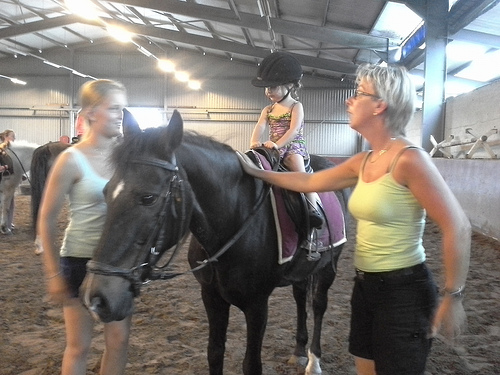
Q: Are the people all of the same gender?
A: Yes, all the people are female.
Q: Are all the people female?
A: Yes, all the people are female.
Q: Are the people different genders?
A: No, all the people are female.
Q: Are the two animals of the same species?
A: Yes, all the animals are horses.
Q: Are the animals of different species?
A: No, all the animals are horses.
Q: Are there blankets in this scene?
A: Yes, there is a blanket.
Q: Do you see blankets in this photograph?
A: Yes, there is a blanket.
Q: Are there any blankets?
A: Yes, there is a blanket.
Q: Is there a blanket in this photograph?
A: Yes, there is a blanket.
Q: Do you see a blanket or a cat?
A: Yes, there is a blanket.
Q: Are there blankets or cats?
A: Yes, there is a blanket.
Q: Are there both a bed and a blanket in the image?
A: No, there is a blanket but no beds.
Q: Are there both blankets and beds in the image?
A: No, there is a blanket but no beds.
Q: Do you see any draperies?
A: No, there are no draperies.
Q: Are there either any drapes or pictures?
A: No, there are no drapes or pictures.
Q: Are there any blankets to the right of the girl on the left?
A: Yes, there is a blanket to the right of the girl.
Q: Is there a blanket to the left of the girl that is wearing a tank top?
A: No, the blanket is to the right of the girl.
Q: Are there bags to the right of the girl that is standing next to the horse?
A: No, there is a blanket to the right of the girl.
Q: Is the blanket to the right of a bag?
A: No, the blanket is to the right of a girl.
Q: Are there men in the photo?
A: No, there are no men.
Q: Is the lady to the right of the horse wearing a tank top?
A: Yes, the lady is wearing a tank top.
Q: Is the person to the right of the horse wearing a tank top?
A: Yes, the lady is wearing a tank top.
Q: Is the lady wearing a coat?
A: No, the lady is wearing a tank top.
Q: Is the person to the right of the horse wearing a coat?
A: No, the lady is wearing a tank top.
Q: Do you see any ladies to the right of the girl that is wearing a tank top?
A: Yes, there is a lady to the right of the girl.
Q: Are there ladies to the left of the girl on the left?
A: No, the lady is to the right of the girl.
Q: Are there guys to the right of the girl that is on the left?
A: No, there is a lady to the right of the girl.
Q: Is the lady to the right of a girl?
A: Yes, the lady is to the right of a girl.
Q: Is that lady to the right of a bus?
A: No, the lady is to the right of a girl.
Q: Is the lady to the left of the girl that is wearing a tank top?
A: No, the lady is to the right of the girl.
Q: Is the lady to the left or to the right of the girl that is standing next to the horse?
A: The lady is to the right of the girl.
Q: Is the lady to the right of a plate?
A: No, the lady is to the right of the horse.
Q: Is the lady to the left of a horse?
A: No, the lady is to the right of a horse.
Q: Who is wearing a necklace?
A: The lady is wearing a necklace.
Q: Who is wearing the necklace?
A: The lady is wearing a necklace.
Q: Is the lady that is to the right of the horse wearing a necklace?
A: Yes, the lady is wearing a necklace.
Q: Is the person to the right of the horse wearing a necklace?
A: Yes, the lady is wearing a necklace.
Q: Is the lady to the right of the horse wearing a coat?
A: No, the lady is wearing a necklace.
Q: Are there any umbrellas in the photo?
A: No, there are no umbrellas.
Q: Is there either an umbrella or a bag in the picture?
A: No, there are no umbrellas or bags.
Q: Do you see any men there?
A: No, there are no men.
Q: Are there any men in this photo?
A: No, there are no men.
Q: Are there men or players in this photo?
A: No, there are no men or players.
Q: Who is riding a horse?
A: The girl is riding a horse.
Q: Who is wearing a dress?
A: The girl is wearing a dress.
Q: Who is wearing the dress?
A: The girl is wearing a dress.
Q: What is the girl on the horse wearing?
A: The girl is wearing a dress.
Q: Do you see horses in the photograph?
A: Yes, there is a horse.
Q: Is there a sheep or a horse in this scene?
A: Yes, there is a horse.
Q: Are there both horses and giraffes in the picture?
A: No, there is a horse but no giraffes.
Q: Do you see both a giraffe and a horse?
A: No, there is a horse but no giraffes.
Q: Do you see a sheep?
A: No, there is no sheep.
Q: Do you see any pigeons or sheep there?
A: No, there are no sheep or pigeons.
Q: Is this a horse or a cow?
A: This is a horse.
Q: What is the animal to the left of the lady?
A: The animal is a horse.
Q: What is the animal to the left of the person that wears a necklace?
A: The animal is a horse.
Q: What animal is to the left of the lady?
A: The animal is a horse.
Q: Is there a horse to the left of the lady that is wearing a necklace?
A: Yes, there is a horse to the left of the lady.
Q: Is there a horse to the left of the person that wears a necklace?
A: Yes, there is a horse to the left of the lady.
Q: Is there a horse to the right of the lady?
A: No, the horse is to the left of the lady.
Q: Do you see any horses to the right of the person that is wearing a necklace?
A: No, the horse is to the left of the lady.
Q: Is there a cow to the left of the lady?
A: No, there is a horse to the left of the lady.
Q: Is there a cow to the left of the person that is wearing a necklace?
A: No, there is a horse to the left of the lady.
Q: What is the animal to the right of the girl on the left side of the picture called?
A: The animal is a horse.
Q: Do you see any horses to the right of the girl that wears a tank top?
A: Yes, there is a horse to the right of the girl.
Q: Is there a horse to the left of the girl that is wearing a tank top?
A: No, the horse is to the right of the girl.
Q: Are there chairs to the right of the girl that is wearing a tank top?
A: No, there is a horse to the right of the girl.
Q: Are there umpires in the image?
A: No, there are no umpires.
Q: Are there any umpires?
A: No, there are no umpires.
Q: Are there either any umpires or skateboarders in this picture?
A: No, there are no umpires or skateboarders.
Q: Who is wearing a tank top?
A: The girl is wearing a tank top.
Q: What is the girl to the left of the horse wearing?
A: The girl is wearing a tank top.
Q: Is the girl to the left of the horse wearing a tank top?
A: Yes, the girl is wearing a tank top.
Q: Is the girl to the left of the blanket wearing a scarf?
A: No, the girl is wearing a tank top.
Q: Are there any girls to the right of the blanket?
A: No, the girl is to the left of the blanket.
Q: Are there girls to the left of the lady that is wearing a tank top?
A: Yes, there is a girl to the left of the lady.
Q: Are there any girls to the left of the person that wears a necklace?
A: Yes, there is a girl to the left of the lady.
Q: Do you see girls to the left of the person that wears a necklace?
A: Yes, there is a girl to the left of the lady.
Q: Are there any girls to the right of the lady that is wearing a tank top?
A: No, the girl is to the left of the lady.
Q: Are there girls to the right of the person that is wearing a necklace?
A: No, the girl is to the left of the lady.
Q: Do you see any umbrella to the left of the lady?
A: No, there is a girl to the left of the lady.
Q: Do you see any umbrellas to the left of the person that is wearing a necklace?
A: No, there is a girl to the left of the lady.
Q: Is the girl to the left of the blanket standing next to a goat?
A: No, the girl is standing next to the horse.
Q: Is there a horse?
A: Yes, there is a horse.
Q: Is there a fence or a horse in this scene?
A: Yes, there is a horse.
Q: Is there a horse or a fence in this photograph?
A: Yes, there is a horse.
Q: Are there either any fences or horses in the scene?
A: Yes, there is a horse.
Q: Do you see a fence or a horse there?
A: Yes, there is a horse.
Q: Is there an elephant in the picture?
A: No, there are no elephants.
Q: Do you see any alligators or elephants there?
A: No, there are no elephants or alligators.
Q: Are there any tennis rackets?
A: No, there are no tennis rackets.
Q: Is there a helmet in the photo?
A: Yes, there is a helmet.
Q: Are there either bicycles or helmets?
A: Yes, there is a helmet.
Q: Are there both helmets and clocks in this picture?
A: No, there is a helmet but no clocks.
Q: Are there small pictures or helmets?
A: Yes, there is a small helmet.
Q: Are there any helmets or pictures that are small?
A: Yes, the helmet is small.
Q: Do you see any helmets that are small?
A: Yes, there is a small helmet.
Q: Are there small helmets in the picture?
A: Yes, there is a small helmet.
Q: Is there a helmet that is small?
A: Yes, there is a helmet that is small.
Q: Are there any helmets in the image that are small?
A: Yes, there is a helmet that is small.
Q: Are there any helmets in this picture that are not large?
A: Yes, there is a small helmet.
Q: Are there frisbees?
A: No, there are no frisbees.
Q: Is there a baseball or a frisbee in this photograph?
A: No, there are no frisbees or baseballs.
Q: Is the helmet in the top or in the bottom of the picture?
A: The helmet is in the top of the image.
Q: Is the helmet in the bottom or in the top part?
A: The helmet is in the top of the image.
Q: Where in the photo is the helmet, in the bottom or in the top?
A: The helmet is in the top of the image.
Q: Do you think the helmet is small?
A: Yes, the helmet is small.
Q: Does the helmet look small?
A: Yes, the helmet is small.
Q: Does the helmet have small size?
A: Yes, the helmet is small.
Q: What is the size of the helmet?
A: The helmet is small.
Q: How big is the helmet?
A: The helmet is small.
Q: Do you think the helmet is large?
A: No, the helmet is small.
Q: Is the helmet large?
A: No, the helmet is small.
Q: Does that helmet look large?
A: No, the helmet is small.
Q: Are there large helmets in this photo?
A: No, there is a helmet but it is small.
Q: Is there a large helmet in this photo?
A: No, there is a helmet but it is small.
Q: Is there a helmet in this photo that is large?
A: No, there is a helmet but it is small.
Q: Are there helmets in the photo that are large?
A: No, there is a helmet but it is small.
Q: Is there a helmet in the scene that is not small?
A: No, there is a helmet but it is small.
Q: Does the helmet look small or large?
A: The helmet is small.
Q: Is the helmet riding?
A: Yes, the helmet is riding.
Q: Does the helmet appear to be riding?
A: Yes, the helmet is riding.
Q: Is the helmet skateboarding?
A: No, the helmet is riding.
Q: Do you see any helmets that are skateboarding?
A: No, there is a helmet but it is riding.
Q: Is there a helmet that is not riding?
A: No, there is a helmet but it is riding.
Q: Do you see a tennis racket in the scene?
A: No, there are no rackets.